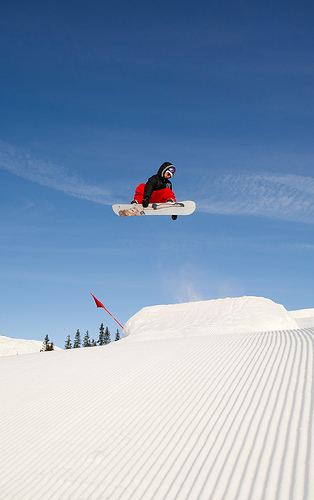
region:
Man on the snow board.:
[106, 122, 278, 298]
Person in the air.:
[99, 154, 280, 252]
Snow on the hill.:
[108, 221, 273, 454]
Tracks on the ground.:
[87, 310, 271, 456]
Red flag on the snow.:
[53, 256, 169, 378]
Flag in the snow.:
[27, 286, 140, 353]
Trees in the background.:
[29, 256, 153, 382]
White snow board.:
[77, 137, 231, 228]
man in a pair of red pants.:
[106, 154, 249, 239]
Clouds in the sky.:
[49, 145, 101, 231]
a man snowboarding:
[103, 158, 199, 220]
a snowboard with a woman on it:
[108, 200, 195, 220]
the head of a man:
[155, 157, 179, 178]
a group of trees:
[37, 319, 121, 353]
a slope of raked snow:
[95, 336, 280, 496]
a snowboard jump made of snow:
[117, 288, 304, 337]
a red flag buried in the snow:
[85, 286, 130, 335]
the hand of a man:
[139, 195, 151, 209]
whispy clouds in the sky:
[209, 161, 308, 238]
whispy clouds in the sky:
[22, 142, 91, 204]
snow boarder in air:
[104, 135, 199, 236]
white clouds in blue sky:
[235, 198, 265, 239]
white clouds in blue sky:
[210, 235, 248, 264]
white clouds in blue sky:
[116, 281, 144, 297]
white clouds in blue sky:
[85, 22, 134, 77]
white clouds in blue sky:
[170, 21, 232, 88]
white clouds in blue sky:
[31, 33, 74, 84]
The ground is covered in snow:
[27, 335, 305, 492]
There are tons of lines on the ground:
[97, 341, 309, 483]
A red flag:
[74, 287, 148, 336]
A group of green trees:
[36, 324, 116, 345]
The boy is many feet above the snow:
[100, 153, 235, 356]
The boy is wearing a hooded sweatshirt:
[134, 156, 181, 199]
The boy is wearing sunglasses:
[161, 168, 175, 177]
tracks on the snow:
[77, 352, 264, 443]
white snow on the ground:
[111, 355, 240, 436]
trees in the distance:
[37, 314, 121, 364]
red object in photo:
[80, 280, 130, 336]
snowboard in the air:
[95, 186, 199, 239]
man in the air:
[110, 152, 205, 221]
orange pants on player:
[121, 184, 181, 210]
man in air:
[105, 129, 201, 229]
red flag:
[78, 283, 143, 348]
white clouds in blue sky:
[184, 49, 221, 69]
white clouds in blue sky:
[244, 182, 281, 215]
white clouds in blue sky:
[109, 253, 138, 270]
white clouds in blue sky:
[17, 160, 48, 185]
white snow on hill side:
[90, 383, 123, 410]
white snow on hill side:
[164, 460, 197, 489]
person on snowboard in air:
[103, 154, 202, 229]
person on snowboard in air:
[101, 164, 208, 227]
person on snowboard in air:
[110, 163, 210, 227]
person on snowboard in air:
[110, 163, 210, 232]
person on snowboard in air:
[106, 165, 203, 226]